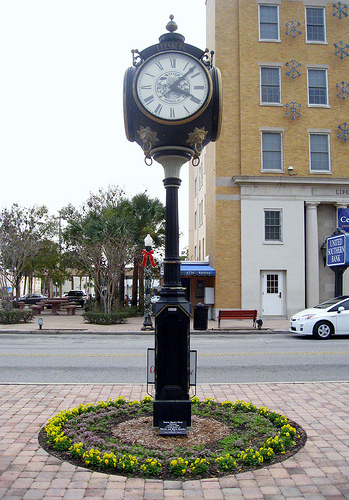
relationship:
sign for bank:
[324, 233, 348, 267] [329, 253, 343, 264]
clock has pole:
[119, 10, 227, 439] [153, 151, 197, 439]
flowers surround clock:
[41, 394, 301, 481] [119, 10, 227, 439]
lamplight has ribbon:
[139, 230, 157, 333] [141, 247, 157, 271]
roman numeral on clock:
[166, 55, 181, 70] [119, 10, 227, 439]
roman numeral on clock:
[153, 58, 167, 74] [119, 10, 227, 439]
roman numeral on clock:
[141, 68, 159, 80] [119, 10, 227, 439]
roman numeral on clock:
[134, 81, 157, 95] [119, 10, 227, 439]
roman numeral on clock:
[142, 94, 156, 107] [119, 10, 227, 439]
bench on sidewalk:
[214, 307, 259, 332] [0, 316, 292, 335]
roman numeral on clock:
[154, 101, 167, 116] [119, 10, 227, 439]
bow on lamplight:
[141, 247, 157, 271] [139, 230, 157, 333]